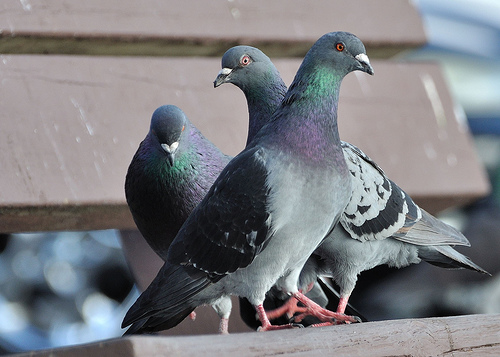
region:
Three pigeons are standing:
[118, 23, 495, 353]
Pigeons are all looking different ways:
[107, 19, 489, 351]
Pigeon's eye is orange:
[333, 39, 347, 55]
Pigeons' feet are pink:
[202, 283, 370, 335]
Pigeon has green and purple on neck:
[278, 23, 378, 183]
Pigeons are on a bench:
[3, 1, 496, 352]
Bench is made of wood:
[1, 3, 496, 354]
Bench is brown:
[1, 1, 498, 354]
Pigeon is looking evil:
[138, 103, 197, 170]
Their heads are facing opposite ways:
[210, 20, 382, 127]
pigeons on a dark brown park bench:
[3, 1, 495, 351]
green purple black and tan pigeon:
[118, 28, 372, 334]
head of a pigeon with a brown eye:
[308, 29, 375, 77]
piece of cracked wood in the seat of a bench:
[28, 308, 494, 353]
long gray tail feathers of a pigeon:
[387, 200, 492, 278]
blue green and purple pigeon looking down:
[126, 102, 232, 252]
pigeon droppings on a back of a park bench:
[416, 56, 481, 171]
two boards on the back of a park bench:
[3, 1, 490, 232]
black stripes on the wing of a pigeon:
[347, 150, 421, 243]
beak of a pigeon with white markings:
[161, 137, 180, 164]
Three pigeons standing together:
[114, 33, 494, 350]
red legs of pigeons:
[233, 297, 381, 339]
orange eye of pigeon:
[331, 35, 351, 58]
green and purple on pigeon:
[257, 67, 356, 184]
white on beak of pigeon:
[151, 132, 188, 155]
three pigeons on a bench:
[91, 14, 489, 351]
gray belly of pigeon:
[266, 168, 351, 294]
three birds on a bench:
[78, 32, 498, 347]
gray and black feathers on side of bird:
[330, 142, 462, 251]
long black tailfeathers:
[91, 263, 198, 355]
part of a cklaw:
[273, 315, 303, 341]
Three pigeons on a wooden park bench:
[78, 9, 492, 344]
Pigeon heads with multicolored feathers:
[101, 23, 390, 187]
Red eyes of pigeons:
[173, 33, 363, 158]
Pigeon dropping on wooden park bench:
[11, 4, 458, 187]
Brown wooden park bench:
[8, 8, 490, 351]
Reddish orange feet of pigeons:
[164, 260, 374, 350]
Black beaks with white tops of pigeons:
[156, 48, 375, 170]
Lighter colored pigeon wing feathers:
[311, 115, 424, 271]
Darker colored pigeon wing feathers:
[131, 142, 281, 347]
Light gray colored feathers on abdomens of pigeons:
[191, 144, 426, 326]